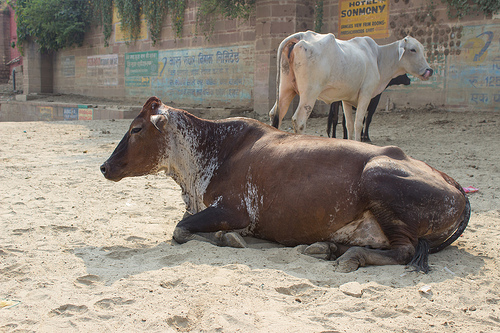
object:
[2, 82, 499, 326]
ground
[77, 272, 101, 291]
track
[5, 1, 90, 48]
shrub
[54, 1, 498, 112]
wall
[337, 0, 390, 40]
sign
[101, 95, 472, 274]
cow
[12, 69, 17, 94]
post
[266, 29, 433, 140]
heifer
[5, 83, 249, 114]
walkway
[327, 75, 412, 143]
calf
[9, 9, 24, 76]
door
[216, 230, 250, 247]
hoof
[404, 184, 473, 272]
tail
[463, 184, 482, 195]
trash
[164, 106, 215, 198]
neck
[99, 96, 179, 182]
head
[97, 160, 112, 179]
nose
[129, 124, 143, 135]
eye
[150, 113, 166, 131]
ear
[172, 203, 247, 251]
leg